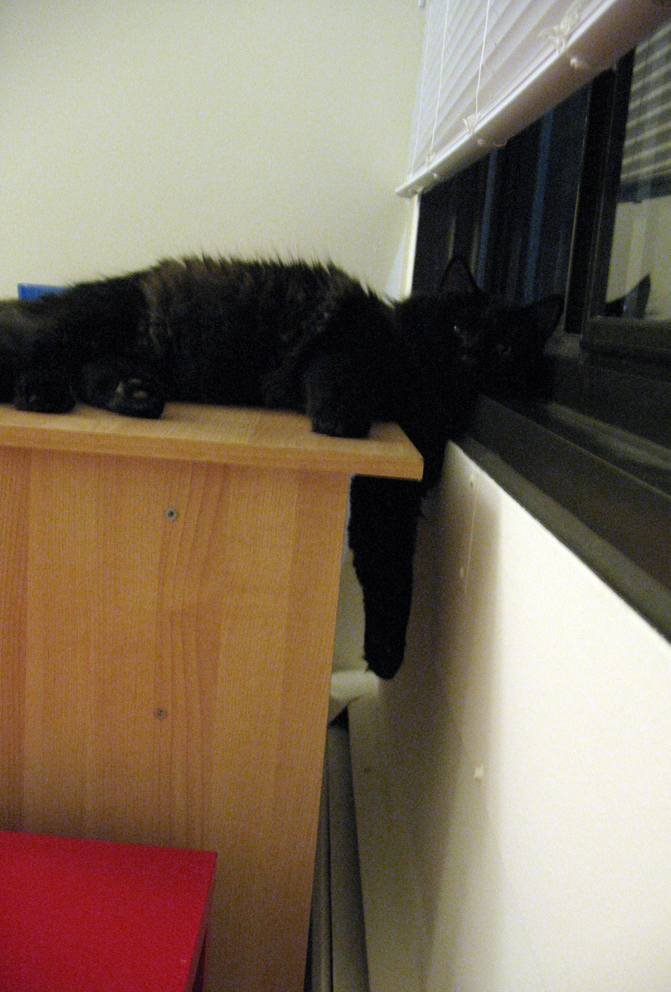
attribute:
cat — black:
[47, 262, 549, 427]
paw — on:
[304, 396, 375, 443]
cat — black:
[31, 215, 585, 736]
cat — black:
[81, 116, 565, 482]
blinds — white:
[393, 2, 670, 198]